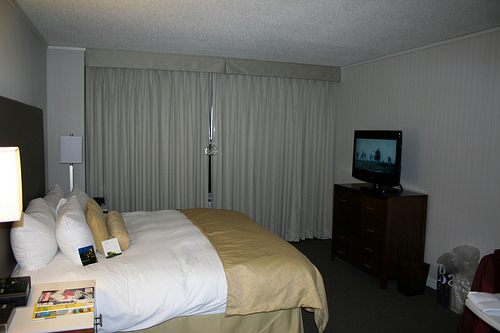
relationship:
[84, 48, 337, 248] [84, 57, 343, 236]
curtains on window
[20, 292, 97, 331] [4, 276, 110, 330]
surface on cupboard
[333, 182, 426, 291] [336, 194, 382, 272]
chest of drawers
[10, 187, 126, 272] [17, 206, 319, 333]
pillows on bed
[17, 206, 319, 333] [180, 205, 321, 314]
bed has cover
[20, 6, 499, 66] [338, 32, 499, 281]
ceiling above wall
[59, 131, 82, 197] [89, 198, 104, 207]
lamp on table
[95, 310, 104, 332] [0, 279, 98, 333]
handle on cupboard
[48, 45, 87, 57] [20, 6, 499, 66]
edge of ceiling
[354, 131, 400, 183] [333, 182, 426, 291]
tv on chest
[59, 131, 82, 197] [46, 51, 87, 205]
lamp toward wall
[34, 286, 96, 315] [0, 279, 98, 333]
magazines on cupboard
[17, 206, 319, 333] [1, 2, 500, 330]
bed in bedroom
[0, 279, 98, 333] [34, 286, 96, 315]
cupboard has magazines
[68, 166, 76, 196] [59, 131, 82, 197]
column of lamp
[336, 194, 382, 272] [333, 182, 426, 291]
drawers in chest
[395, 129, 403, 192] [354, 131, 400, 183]
edge of tv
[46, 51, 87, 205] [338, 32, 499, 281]
white of wall